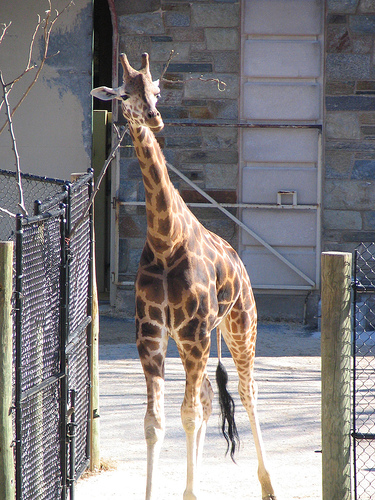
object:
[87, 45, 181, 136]
head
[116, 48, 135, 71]
horns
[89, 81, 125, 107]
ear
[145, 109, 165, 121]
nose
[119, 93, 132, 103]
right eye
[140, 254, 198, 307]
pattern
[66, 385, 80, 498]
bar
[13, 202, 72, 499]
door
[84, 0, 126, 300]
pole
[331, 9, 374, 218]
wall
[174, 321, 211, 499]
legs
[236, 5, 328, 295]
ladder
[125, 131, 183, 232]
giraffe neck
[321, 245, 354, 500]
pole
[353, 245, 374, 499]
fence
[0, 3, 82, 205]
limbs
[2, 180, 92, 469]
fence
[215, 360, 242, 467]
tail end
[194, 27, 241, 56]
bricks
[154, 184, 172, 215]
spots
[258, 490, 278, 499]
hoof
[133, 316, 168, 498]
front legs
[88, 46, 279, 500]
giraffe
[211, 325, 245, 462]
tail